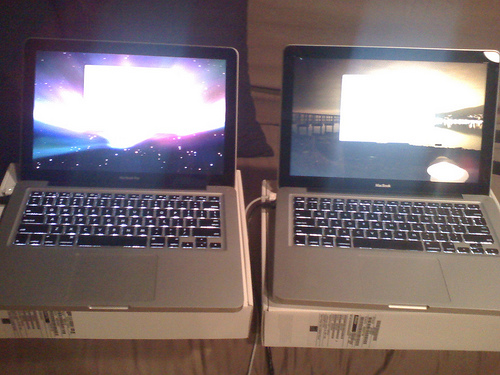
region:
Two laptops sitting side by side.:
[3, 20, 498, 317]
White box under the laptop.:
[257, 300, 499, 361]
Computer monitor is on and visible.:
[271, 37, 498, 197]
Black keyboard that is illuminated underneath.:
[289, 192, 499, 259]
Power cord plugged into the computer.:
[249, 185, 281, 209]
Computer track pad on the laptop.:
[346, 247, 458, 312]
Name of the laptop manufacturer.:
[369, 177, 396, 189]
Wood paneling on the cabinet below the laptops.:
[68, 347, 230, 374]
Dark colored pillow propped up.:
[46, 10, 260, 31]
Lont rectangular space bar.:
[350, 235, 425, 252]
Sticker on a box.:
[308, 320, 385, 352]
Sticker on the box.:
[0, 313, 82, 342]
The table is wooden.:
[158, 345, 234, 372]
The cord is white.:
[232, 332, 272, 374]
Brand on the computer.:
[365, 172, 409, 202]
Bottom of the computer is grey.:
[294, 259, 356, 291]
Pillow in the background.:
[48, 0, 153, 41]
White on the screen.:
[349, 92, 395, 124]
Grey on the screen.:
[290, 73, 340, 111]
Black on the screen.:
[92, 156, 148, 176]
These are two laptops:
[0, 28, 497, 330]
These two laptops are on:
[0, 26, 499, 354]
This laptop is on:
[0, 26, 258, 353]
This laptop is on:
[254, 24, 499, 356]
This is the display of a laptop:
[27, 43, 232, 188]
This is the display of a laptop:
[287, 50, 488, 191]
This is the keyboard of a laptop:
[3, 186, 237, 254]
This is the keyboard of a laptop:
[282, 190, 499, 264]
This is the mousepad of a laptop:
[66, 246, 165, 304]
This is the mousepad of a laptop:
[350, 248, 458, 305]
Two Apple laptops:
[7, 61, 484, 321]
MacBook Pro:
[270, 75, 492, 315]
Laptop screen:
[5, 25, 235, 185]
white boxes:
[0, 295, 495, 357]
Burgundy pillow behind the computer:
[10, 1, 290, 151]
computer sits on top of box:
[0, 127, 252, 352]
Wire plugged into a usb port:
[248, 183, 290, 243]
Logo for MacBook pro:
[364, 175, 404, 190]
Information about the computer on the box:
[293, 308, 413, 358]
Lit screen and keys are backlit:
[11, 100, 240, 270]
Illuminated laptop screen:
[285, 53, 495, 221]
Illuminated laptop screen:
[35, 53, 223, 185]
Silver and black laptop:
[3, 33, 238, 327]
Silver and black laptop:
[282, 21, 489, 296]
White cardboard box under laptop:
[3, 308, 248, 345]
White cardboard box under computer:
[262, 302, 494, 355]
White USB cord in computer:
[248, 173, 292, 233]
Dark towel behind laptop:
[9, 4, 284, 153]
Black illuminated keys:
[21, 181, 230, 260]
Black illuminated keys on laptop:
[288, 188, 495, 258]